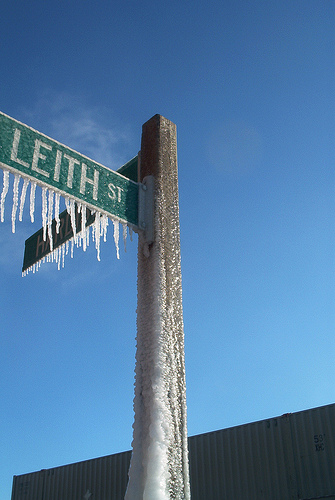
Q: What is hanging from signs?
A: Icicles.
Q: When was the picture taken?
A: Daytime.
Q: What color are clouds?
A: White.